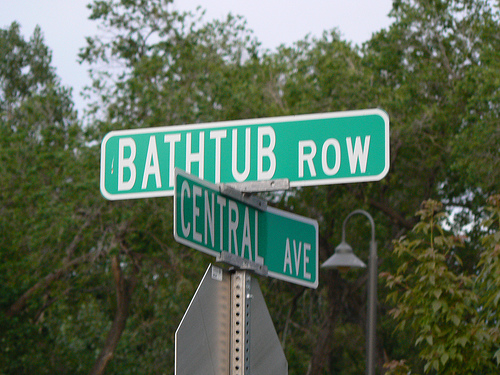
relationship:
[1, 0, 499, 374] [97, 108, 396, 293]
trees are behind street sign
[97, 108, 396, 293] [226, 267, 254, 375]
street sign on top of pole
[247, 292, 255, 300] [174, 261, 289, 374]
nut holding stop sign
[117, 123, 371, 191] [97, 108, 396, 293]
words are on street sign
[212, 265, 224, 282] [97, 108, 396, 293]
label attached to street sign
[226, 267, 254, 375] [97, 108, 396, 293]
pole holding street sign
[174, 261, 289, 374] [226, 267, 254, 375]
stop sign attached to pole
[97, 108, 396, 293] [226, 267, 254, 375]
street sign on pole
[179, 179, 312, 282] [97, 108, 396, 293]
words are on street sign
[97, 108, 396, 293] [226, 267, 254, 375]
street sign attached to pole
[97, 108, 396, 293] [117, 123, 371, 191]
street sign has words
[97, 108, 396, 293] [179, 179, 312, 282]
street sign has words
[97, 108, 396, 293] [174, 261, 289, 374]
street sign above stop sign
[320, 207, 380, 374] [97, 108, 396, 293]
lights pole behind street sign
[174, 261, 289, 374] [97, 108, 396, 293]
stop sign under street sign